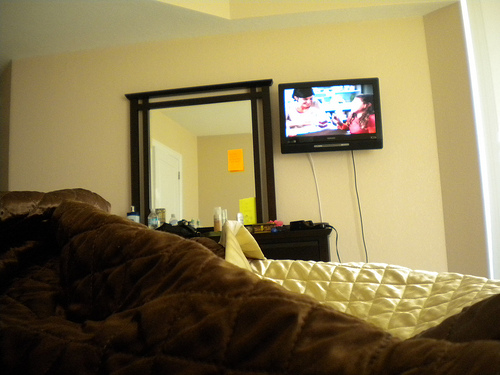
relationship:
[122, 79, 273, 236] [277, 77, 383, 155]
mirror near television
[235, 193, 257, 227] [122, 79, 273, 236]
stick note on mirror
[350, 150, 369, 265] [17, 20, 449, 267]
chord on wall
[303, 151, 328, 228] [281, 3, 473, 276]
cord on wall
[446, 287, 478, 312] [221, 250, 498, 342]
square of blanket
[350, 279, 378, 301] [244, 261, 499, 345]
white square of blanket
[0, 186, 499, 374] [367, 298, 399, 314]
bedspread has square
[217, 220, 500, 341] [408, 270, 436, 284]
blanket has white square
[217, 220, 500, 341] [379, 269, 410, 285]
blanket has square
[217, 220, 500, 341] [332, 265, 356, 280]
blanket has white square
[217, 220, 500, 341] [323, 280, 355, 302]
blanket has square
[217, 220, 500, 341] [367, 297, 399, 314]
blanket has square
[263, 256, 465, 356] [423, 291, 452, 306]
blanket has square